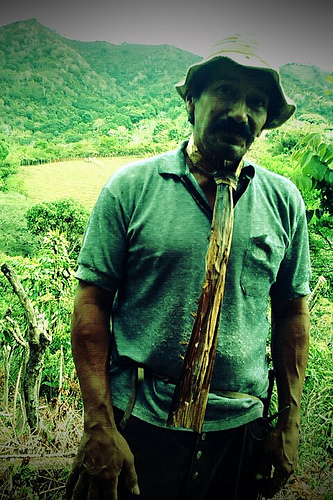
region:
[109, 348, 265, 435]
rope tied around waist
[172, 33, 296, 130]
man wearing a bucket hat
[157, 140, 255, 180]
collar attached to shirt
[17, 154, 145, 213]
grassy field surrounded by mountains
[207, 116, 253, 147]
man has a bushy mustache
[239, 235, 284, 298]
a pocket is sewn onto the shirt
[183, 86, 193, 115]
ear visible under hat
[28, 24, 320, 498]
man standing on a field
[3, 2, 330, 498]
field is covered with vegetation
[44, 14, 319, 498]
man wearing a hat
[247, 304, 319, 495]
veins are visible over arm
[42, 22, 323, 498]
man wearing a green shirt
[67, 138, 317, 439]
the shirt is color green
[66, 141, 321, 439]
shirt has a pocket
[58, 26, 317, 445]
man has a long leave attached to his neck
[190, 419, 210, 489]
black pants have buttons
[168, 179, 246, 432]
man wearing long yellow tie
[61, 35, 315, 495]
dark Hispanic man with mustache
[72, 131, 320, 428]
short green polo shirt on man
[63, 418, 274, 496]
black pants on man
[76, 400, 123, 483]
pronounced veins in hand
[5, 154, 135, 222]
grassy field in background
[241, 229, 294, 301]
pocket on green shirt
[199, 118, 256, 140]
large bushy black mustache on man's face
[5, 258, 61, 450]
leafless dead tree trunk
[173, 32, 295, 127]
white hat on man's head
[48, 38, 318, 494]
this is a person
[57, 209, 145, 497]
this is a hand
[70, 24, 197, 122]
this is a mountain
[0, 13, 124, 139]
this is a mountain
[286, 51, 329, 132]
this is a mountain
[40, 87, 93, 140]
bushy trees on the mountain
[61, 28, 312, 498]
man with a mustache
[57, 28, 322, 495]
man wearing a hat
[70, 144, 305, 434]
green short sleeve shirt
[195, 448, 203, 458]
button on pants fly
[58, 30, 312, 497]
man with dark eyes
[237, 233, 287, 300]
pocket on front of tshirt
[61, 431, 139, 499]
right hand of man in jungle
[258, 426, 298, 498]
left hand of man in jungle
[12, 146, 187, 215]
large open area in mountains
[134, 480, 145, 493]
The man's fingernails.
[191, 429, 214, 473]
The buttons on the man's pants.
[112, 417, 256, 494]
The man is wearing a black pant.